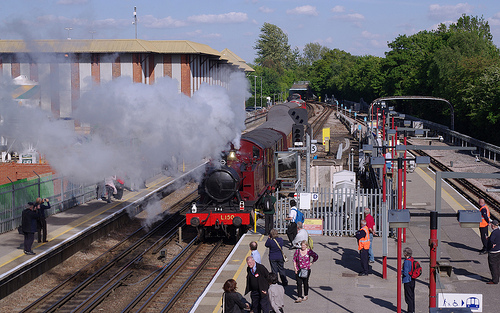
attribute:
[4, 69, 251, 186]
smoke — gray, white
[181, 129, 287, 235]
train engine — black, red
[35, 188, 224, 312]
train tracks — empty, metal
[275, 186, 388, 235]
fence — gray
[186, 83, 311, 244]
train — red, black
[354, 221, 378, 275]
man — standing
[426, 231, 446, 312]
light pole — red, metal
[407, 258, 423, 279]
backpack — red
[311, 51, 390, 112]
trees — green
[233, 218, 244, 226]
bumper — round, metal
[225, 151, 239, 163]
bell — gold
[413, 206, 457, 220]
arm — black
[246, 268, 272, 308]
suit — black, dark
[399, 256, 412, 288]
shirt — blue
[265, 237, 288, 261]
shirt — purple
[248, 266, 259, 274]
shirt — blue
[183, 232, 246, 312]
stripe — white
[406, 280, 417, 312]
pants — black